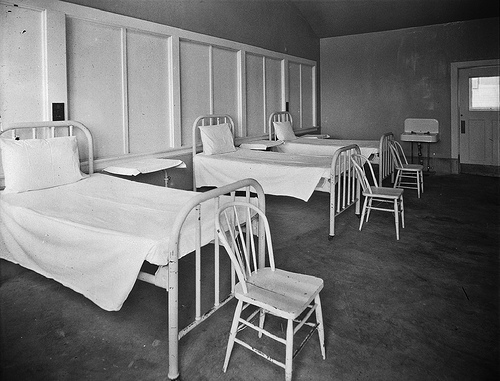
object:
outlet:
[52, 103, 64, 121]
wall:
[0, 14, 95, 102]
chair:
[215, 202, 327, 381]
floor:
[0, 171, 498, 380]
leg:
[285, 320, 294, 381]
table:
[104, 158, 184, 187]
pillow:
[0, 135, 90, 195]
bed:
[268, 111, 395, 186]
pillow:
[198, 123, 238, 156]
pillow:
[273, 121, 298, 140]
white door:
[459, 69, 500, 167]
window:
[468, 76, 500, 111]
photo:
[0, 0, 499, 381]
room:
[0, 0, 500, 381]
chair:
[350, 153, 405, 241]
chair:
[388, 140, 425, 198]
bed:
[0, 121, 266, 380]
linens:
[0, 172, 258, 313]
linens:
[193, 146, 350, 203]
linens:
[272, 138, 380, 166]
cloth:
[102, 158, 187, 177]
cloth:
[239, 140, 285, 150]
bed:
[192, 114, 361, 241]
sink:
[400, 118, 440, 143]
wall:
[318, 0, 451, 119]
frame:
[168, 230, 179, 381]